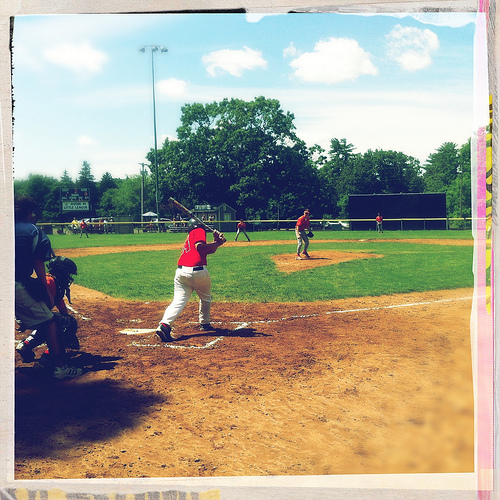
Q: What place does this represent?
A: It represents the field.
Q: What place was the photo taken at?
A: It was taken at the field.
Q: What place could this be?
A: It is a field.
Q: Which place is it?
A: It is a field.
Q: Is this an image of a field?
A: Yes, it is showing a field.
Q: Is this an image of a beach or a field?
A: It is showing a field.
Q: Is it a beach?
A: No, it is a field.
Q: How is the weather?
A: It is sunny.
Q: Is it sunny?
A: Yes, it is sunny.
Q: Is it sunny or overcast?
A: It is sunny.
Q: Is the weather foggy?
A: No, it is sunny.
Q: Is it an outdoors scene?
A: Yes, it is outdoors.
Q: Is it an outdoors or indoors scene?
A: It is outdoors.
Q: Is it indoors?
A: No, it is outdoors.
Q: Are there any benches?
A: No, there are no benches.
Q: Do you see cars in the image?
A: No, there are no cars.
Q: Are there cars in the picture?
A: No, there are no cars.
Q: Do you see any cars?
A: No, there are no cars.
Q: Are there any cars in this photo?
A: No, there are no cars.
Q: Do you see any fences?
A: Yes, there is a fence.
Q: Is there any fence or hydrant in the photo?
A: Yes, there is a fence.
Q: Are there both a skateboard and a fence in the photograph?
A: No, there is a fence but no skateboards.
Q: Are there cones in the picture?
A: No, there are no cones.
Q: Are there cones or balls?
A: No, there are no cones or balls.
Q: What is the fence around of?
A: The fence is around the field.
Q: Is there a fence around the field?
A: Yes, there is a fence around the field.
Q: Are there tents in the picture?
A: No, there are no tents.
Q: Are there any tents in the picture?
A: No, there are no tents.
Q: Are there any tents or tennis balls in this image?
A: No, there are no tents or tennis balls.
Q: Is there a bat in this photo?
A: Yes, there is a bat.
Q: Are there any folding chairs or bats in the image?
A: Yes, there is a bat.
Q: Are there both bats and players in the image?
A: Yes, there are both a bat and a player.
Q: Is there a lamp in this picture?
A: No, there are no lamps.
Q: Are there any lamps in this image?
A: No, there are no lamps.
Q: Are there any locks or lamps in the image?
A: No, there are no lamps or locks.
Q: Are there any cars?
A: No, there are no cars.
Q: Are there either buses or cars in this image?
A: No, there are no cars or buses.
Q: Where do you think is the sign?
A: The sign is at the game.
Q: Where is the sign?
A: The sign is at the game.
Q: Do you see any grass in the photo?
A: Yes, there is grass.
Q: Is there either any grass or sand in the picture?
A: Yes, there is grass.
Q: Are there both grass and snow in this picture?
A: No, there is grass but no snow.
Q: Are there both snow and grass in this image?
A: No, there is grass but no snow.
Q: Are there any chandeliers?
A: No, there are no chandeliers.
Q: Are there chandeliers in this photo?
A: No, there are no chandeliers.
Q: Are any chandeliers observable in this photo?
A: No, there are no chandeliers.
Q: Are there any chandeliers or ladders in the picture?
A: No, there are no chandeliers or ladders.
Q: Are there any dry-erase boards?
A: No, there are no dry-erase boards.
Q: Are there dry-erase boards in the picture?
A: No, there are no dry-erase boards.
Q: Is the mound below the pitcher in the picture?
A: Yes, the mound is below the pitcher.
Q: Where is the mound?
A: The mound is at the game.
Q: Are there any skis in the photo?
A: No, there are no skis.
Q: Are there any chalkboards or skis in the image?
A: No, there are no skis or chalkboards.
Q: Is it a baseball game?
A: Yes, that is a baseball game.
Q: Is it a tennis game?
A: No, that is a baseball game.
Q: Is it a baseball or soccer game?
A: That is a baseball game.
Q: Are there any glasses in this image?
A: No, there are no glasses.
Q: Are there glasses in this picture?
A: No, there are no glasses.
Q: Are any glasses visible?
A: No, there are no glasses.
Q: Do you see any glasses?
A: No, there are no glasses.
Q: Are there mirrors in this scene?
A: No, there are no mirrors.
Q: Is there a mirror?
A: No, there are no mirrors.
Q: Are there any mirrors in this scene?
A: No, there are no mirrors.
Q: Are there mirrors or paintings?
A: No, there are no mirrors or paintings.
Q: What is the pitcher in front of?
A: The pitcher is in front of the tree.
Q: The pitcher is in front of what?
A: The pitcher is in front of the tree.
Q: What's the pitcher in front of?
A: The pitcher is in front of the tree.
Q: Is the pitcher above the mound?
A: Yes, the pitcher is above the mound.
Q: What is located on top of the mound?
A: The pitcher is on top of the mound.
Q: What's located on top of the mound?
A: The pitcher is on top of the mound.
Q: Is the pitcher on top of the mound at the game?
A: Yes, the pitcher is on top of the mound.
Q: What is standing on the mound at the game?
A: The pitcher is standing on the mound.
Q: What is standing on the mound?
A: The pitcher is standing on the mound.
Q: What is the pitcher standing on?
A: The pitcher is standing on the mound.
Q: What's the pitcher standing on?
A: The pitcher is standing on the mound.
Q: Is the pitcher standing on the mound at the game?
A: Yes, the pitcher is standing on the mound.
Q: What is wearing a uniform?
A: The pitcher is wearing a uniform.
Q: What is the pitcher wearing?
A: The pitcher is wearing a uniform.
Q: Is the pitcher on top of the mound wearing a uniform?
A: Yes, the pitcher is wearing a uniform.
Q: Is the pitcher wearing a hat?
A: No, the pitcher is wearing a uniform.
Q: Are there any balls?
A: No, there are no balls.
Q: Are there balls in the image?
A: No, there are no balls.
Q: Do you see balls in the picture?
A: No, there are no balls.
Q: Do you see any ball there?
A: No, there are no balls.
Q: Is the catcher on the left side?
A: Yes, the catcher is on the left of the image.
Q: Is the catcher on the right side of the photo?
A: No, the catcher is on the left of the image.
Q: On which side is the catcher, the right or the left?
A: The catcher is on the left of the image.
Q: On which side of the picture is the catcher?
A: The catcher is on the left of the image.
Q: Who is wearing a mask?
A: The catcher is wearing a mask.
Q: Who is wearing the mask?
A: The catcher is wearing a mask.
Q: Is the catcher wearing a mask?
A: Yes, the catcher is wearing a mask.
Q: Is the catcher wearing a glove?
A: No, the catcher is wearing a mask.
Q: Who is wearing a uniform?
A: The catcher is wearing a uniform.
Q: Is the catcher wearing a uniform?
A: Yes, the catcher is wearing a uniform.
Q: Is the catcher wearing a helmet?
A: No, the catcher is wearing a uniform.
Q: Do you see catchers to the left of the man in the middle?
A: Yes, there is a catcher to the left of the man.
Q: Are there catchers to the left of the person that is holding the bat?
A: Yes, there is a catcher to the left of the man.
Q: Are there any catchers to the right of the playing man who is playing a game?
A: No, the catcher is to the left of the man.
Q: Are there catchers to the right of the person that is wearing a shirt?
A: No, the catcher is to the left of the man.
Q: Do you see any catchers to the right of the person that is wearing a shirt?
A: No, the catcher is to the left of the man.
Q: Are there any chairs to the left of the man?
A: No, there is a catcher to the left of the man.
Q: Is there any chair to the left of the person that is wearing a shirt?
A: No, there is a catcher to the left of the man.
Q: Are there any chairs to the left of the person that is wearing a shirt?
A: No, there is a catcher to the left of the man.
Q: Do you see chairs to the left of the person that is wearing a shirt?
A: No, there is a catcher to the left of the man.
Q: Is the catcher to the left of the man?
A: Yes, the catcher is to the left of the man.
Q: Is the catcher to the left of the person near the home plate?
A: Yes, the catcher is to the left of the man.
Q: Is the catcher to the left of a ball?
A: No, the catcher is to the left of the man.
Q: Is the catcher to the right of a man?
A: No, the catcher is to the left of a man.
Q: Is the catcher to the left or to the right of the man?
A: The catcher is to the left of the man.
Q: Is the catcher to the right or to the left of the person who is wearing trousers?
A: The catcher is to the left of the man.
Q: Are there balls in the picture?
A: No, there are no balls.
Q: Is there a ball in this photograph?
A: No, there are no balls.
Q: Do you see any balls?
A: No, there are no balls.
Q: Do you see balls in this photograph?
A: No, there are no balls.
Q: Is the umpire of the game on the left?
A: Yes, the umpire is on the left of the image.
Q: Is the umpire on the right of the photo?
A: No, the umpire is on the left of the image.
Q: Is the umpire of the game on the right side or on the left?
A: The umpire is on the left of the image.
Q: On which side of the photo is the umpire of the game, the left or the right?
A: The umpire is on the left of the image.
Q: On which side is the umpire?
A: The umpire is on the left of the image.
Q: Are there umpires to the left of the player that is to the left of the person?
A: Yes, there is an umpire to the left of the player.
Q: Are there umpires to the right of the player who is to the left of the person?
A: No, the umpire is to the left of the player.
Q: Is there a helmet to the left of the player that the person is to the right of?
A: No, there is an umpire to the left of the player.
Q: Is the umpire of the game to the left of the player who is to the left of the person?
A: Yes, the umpire is to the left of the player.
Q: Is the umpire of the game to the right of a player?
A: No, the umpire is to the left of a player.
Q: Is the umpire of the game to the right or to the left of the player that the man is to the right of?
A: The umpire is to the left of the player.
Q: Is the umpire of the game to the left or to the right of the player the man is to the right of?
A: The umpire is to the left of the player.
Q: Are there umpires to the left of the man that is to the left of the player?
A: Yes, there is an umpire to the left of the man.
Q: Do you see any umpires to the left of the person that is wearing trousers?
A: Yes, there is an umpire to the left of the man.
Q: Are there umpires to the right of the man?
A: No, the umpire is to the left of the man.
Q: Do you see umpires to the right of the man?
A: No, the umpire is to the left of the man.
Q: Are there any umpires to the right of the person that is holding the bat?
A: No, the umpire is to the left of the man.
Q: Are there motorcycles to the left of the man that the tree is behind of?
A: No, there is an umpire to the left of the man.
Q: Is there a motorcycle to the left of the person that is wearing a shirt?
A: No, there is an umpire to the left of the man.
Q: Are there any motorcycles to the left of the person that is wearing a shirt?
A: No, there is an umpire to the left of the man.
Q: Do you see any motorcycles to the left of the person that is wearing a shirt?
A: No, there is an umpire to the left of the man.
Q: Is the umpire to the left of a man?
A: Yes, the umpire is to the left of a man.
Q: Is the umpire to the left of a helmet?
A: No, the umpire is to the left of a man.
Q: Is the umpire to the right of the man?
A: No, the umpire is to the left of the man.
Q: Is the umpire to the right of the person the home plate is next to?
A: No, the umpire is to the left of the man.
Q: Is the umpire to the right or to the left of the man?
A: The umpire is to the left of the man.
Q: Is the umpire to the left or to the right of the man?
A: The umpire is to the left of the man.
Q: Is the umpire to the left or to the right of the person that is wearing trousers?
A: The umpire is to the left of the man.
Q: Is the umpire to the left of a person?
A: Yes, the umpire is to the left of a person.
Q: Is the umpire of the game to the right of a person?
A: No, the umpire is to the left of a person.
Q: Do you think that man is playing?
A: Yes, the man is playing.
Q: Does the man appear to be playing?
A: Yes, the man is playing.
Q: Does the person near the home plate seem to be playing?
A: Yes, the man is playing.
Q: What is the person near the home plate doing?
A: The man is playing.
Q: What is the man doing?
A: The man is playing.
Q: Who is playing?
A: The man is playing.